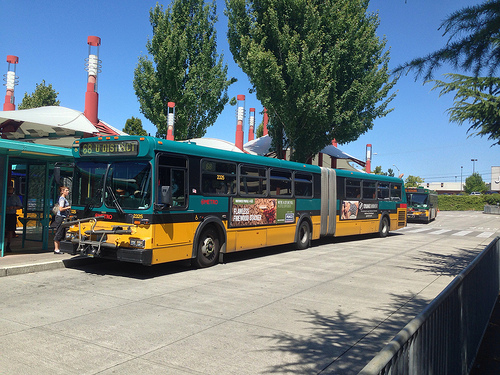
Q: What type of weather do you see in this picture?
A: It is clear.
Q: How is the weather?
A: It is clear.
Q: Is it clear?
A: Yes, it is clear.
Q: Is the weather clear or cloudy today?
A: It is clear.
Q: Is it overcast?
A: No, it is clear.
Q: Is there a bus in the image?
A: Yes, there is a bus.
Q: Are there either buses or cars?
A: Yes, there is a bus.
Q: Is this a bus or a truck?
A: This is a bus.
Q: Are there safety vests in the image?
A: No, there are no safety vests.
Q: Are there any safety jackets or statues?
A: No, there are no safety jackets or statues.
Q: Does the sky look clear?
A: Yes, the sky is clear.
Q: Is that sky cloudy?
A: No, the sky is clear.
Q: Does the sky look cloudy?
A: No, the sky is clear.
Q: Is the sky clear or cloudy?
A: The sky is clear.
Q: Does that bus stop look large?
A: Yes, the bus stop is large.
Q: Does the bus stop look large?
A: Yes, the bus stop is large.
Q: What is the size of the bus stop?
A: The bus stop is large.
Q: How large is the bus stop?
A: The bus stop is large.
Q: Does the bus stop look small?
A: No, the bus stop is large.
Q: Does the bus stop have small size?
A: No, the bus stop is large.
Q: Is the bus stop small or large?
A: The bus stop is large.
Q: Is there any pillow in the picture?
A: No, there are no pillows.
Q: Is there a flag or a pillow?
A: No, there are no pillows or flags.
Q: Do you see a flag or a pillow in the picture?
A: No, there are no pillows or flags.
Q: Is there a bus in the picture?
A: Yes, there is a bus.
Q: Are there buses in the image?
A: Yes, there is a bus.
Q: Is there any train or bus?
A: Yes, there is a bus.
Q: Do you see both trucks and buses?
A: No, there is a bus but no trucks.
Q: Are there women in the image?
A: Yes, there is a woman.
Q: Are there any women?
A: Yes, there is a woman.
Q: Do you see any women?
A: Yes, there is a woman.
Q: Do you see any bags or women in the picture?
A: Yes, there is a woman.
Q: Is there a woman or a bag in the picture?
A: Yes, there is a woman.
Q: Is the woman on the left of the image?
A: Yes, the woman is on the left of the image.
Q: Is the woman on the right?
A: No, the woman is on the left of the image.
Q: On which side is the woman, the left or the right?
A: The woman is on the left of the image.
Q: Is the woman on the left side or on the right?
A: The woman is on the left of the image.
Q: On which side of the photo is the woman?
A: The woman is on the left of the image.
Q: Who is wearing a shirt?
A: The woman is wearing a shirt.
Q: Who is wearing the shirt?
A: The woman is wearing a shirt.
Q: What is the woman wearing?
A: The woman is wearing a shirt.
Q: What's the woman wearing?
A: The woman is wearing a shirt.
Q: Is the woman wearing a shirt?
A: Yes, the woman is wearing a shirt.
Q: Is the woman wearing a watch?
A: No, the woman is wearing a shirt.